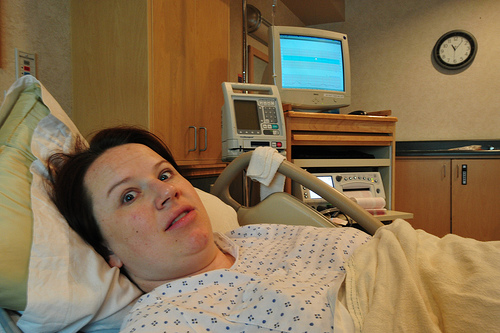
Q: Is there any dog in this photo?
A: No, there are no dogs.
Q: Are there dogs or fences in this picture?
A: No, there are no dogs or fences.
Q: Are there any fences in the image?
A: No, there are no fences.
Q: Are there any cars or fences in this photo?
A: No, there are no fences or cars.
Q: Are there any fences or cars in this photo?
A: No, there are no fences or cars.